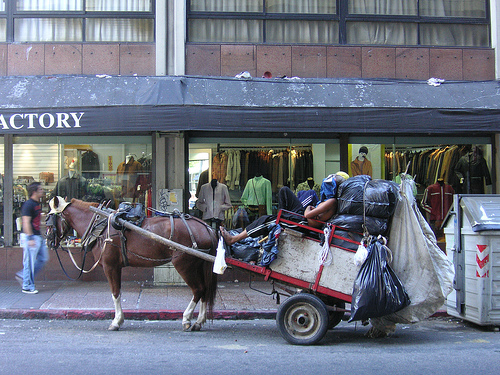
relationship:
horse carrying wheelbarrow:
[37, 194, 228, 330] [217, 162, 416, 338]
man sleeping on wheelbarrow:
[214, 175, 340, 246] [217, 162, 416, 338]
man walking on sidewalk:
[19, 176, 60, 302] [2, 277, 328, 323]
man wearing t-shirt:
[19, 176, 60, 302] [20, 196, 45, 236]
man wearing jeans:
[19, 176, 60, 302] [17, 231, 51, 289]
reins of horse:
[52, 231, 105, 282] [37, 194, 228, 330]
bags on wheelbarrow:
[336, 180, 410, 319] [217, 162, 416, 338]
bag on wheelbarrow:
[391, 183, 456, 329] [217, 162, 416, 338]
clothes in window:
[191, 146, 312, 212] [185, 132, 348, 223]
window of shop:
[185, 132, 348, 223] [0, 74, 499, 253]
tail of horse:
[202, 262, 214, 308] [37, 194, 228, 330]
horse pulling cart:
[37, 194, 228, 330] [217, 162, 416, 338]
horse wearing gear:
[37, 194, 228, 330] [43, 192, 130, 261]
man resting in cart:
[214, 175, 340, 246] [194, 207, 394, 319]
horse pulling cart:
[37, 194, 228, 330] [194, 207, 394, 319]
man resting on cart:
[214, 175, 340, 246] [194, 207, 394, 319]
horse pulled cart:
[37, 194, 228, 330] [194, 207, 394, 319]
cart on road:
[194, 207, 394, 319] [4, 315, 499, 374]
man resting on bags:
[214, 175, 340, 246] [336, 180, 410, 319]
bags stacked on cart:
[336, 180, 410, 319] [194, 207, 394, 319]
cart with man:
[194, 207, 394, 319] [214, 175, 340, 246]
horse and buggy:
[37, 194, 228, 330] [217, 162, 416, 338]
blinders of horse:
[46, 208, 58, 235] [37, 194, 228, 330]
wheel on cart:
[270, 291, 337, 349] [194, 207, 394, 319]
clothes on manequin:
[196, 181, 232, 221] [191, 173, 234, 225]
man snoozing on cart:
[214, 175, 340, 246] [194, 207, 394, 319]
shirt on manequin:
[238, 176, 275, 216] [236, 169, 278, 221]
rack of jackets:
[213, 140, 323, 152] [209, 144, 312, 193]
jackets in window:
[209, 144, 312, 193] [185, 132, 348, 223]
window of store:
[185, 132, 348, 223] [0, 74, 499, 253]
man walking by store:
[19, 176, 60, 302] [0, 74, 499, 253]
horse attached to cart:
[37, 194, 228, 330] [194, 207, 394, 319]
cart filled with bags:
[194, 207, 394, 319] [336, 180, 410, 319]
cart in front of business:
[194, 207, 394, 319] [0, 74, 499, 253]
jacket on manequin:
[423, 183, 456, 220] [424, 177, 462, 234]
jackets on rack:
[209, 144, 312, 193] [213, 140, 323, 152]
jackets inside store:
[209, 144, 312, 193] [0, 74, 499, 253]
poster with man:
[348, 140, 389, 183] [348, 148, 373, 174]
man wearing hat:
[348, 148, 373, 174] [360, 147, 371, 154]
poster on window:
[348, 140, 389, 183] [185, 132, 348, 223]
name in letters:
[1, 110, 86, 135] [57, 112, 87, 129]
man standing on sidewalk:
[19, 176, 60, 302] [2, 277, 328, 323]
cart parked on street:
[194, 207, 394, 319] [4, 315, 499, 374]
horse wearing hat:
[37, 194, 228, 330] [45, 194, 73, 213]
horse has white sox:
[37, 194, 228, 330] [107, 293, 126, 329]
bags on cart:
[336, 180, 410, 319] [194, 207, 394, 319]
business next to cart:
[0, 74, 499, 253] [194, 207, 394, 319]